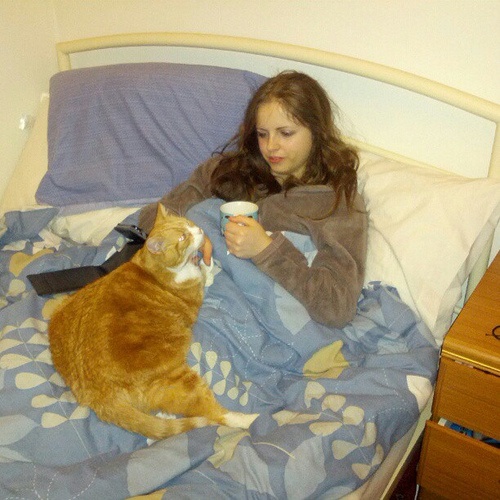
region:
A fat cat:
[41, 204, 218, 444]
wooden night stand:
[411, 248, 498, 481]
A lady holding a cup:
[16, 65, 396, 340]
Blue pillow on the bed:
[44, 73, 289, 213]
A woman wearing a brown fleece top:
[91, 68, 379, 284]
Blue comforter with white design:
[4, 193, 419, 498]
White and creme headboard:
[41, 32, 498, 182]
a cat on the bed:
[41, 200, 265, 452]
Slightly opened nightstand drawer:
[406, 395, 499, 497]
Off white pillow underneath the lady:
[336, 141, 492, 338]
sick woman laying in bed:
[107, 75, 385, 442]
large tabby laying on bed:
[33, 184, 243, 454]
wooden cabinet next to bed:
[438, 285, 495, 497]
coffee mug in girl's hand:
[212, 182, 255, 241]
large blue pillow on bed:
[35, 56, 273, 208]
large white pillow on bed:
[332, 130, 497, 284]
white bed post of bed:
[47, 27, 497, 234]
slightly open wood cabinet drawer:
[416, 432, 498, 486]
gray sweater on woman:
[197, 175, 368, 317]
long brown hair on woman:
[245, 79, 346, 204]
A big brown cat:
[54, 218, 244, 435]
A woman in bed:
[243, 37, 340, 219]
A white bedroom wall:
[415, 24, 492, 78]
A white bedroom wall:
[397, 93, 492, 178]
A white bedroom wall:
[93, 1, 203, 33]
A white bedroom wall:
[7, 5, 60, 69]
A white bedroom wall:
[0, 78, 50, 181]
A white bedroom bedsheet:
[365, 170, 476, 317]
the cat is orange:
[117, 300, 151, 332]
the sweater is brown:
[301, 204, 329, 226]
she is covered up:
[198, 179, 306, 255]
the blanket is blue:
[359, 384, 396, 406]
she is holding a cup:
[218, 196, 264, 230]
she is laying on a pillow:
[322, 168, 380, 236]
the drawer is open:
[431, 414, 476, 449]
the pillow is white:
[391, 194, 421, 227]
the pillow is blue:
[107, 90, 143, 115]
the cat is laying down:
[174, 286, 204, 391]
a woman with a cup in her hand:
[214, 199, 263, 240]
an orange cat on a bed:
[43, 199, 265, 436]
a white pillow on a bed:
[265, 142, 498, 349]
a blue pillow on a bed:
[28, 63, 282, 212]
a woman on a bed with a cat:
[43, 69, 376, 448]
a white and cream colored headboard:
[50, 32, 498, 186]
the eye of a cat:
[176, 230, 188, 242]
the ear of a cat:
[143, 237, 170, 254]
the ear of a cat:
[152, 200, 172, 225]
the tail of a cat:
[98, 389, 251, 450]